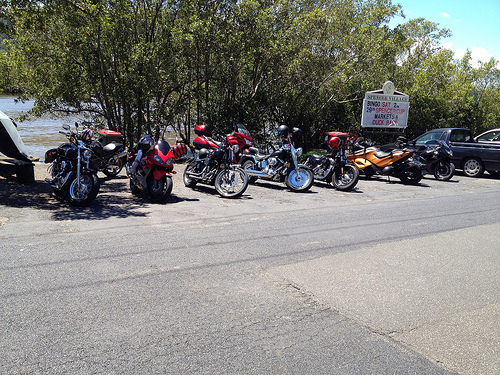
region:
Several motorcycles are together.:
[36, 95, 460, 227]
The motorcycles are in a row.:
[13, 110, 453, 210]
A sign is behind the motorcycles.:
[346, 71, 427, 140]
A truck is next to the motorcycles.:
[404, 115, 499, 178]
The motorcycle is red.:
[116, 126, 195, 206]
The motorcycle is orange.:
[347, 133, 430, 187]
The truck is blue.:
[406, 120, 498, 179]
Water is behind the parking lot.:
[0, 81, 120, 163]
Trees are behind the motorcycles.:
[0, 1, 417, 151]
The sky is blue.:
[391, 1, 496, 63]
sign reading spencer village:
[359, 80, 410, 135]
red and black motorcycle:
[183, 119, 257, 201]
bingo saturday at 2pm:
[363, 100, 409, 110]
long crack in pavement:
[259, 247, 459, 373]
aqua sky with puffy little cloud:
[430, 5, 498, 33]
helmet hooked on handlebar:
[322, 133, 346, 151]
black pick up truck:
[407, 124, 499, 185]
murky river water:
[7, 96, 102, 156]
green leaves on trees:
[95, 15, 217, 75]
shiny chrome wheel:
[281, 158, 321, 192]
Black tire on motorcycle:
[213, 163, 249, 199]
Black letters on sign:
[366, 98, 381, 107]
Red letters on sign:
[372, 118, 384, 126]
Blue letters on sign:
[366, 104, 377, 115]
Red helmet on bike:
[326, 133, 343, 152]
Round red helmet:
[326, 133, 344, 150]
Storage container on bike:
[191, 120, 212, 135]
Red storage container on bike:
[193, 122, 210, 135]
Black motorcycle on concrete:
[177, 136, 250, 198]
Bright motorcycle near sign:
[346, 133, 426, 186]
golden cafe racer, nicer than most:
[343, 136, 429, 192]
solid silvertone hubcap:
[287, 164, 314, 193]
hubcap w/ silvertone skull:
[325, 161, 365, 192]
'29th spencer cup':
[363, 106, 408, 115]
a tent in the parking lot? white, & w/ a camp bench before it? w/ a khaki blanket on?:
[0, 106, 44, 205]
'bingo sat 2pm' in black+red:
[363, 100, 403, 110]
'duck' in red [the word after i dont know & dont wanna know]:
[367, 118, 385, 128]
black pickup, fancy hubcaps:
[405, 126, 498, 183]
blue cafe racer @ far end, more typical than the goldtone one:
[387, 141, 458, 184]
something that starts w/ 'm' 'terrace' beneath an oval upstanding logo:
[363, 77, 413, 104]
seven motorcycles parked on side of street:
[33, 105, 460, 208]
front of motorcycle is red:
[115, 120, 181, 210]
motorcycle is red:
[181, 117, 261, 201]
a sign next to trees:
[356, 70, 416, 136]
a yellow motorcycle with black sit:
[343, 139, 430, 191]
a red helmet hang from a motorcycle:
[317, 130, 348, 161]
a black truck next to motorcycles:
[405, 119, 498, 181]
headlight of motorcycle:
[285, 139, 308, 161]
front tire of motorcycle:
[210, 162, 252, 202]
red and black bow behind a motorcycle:
[191, 116, 214, 144]